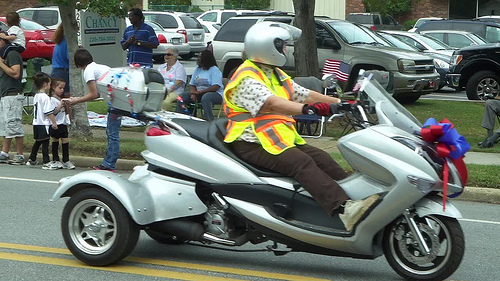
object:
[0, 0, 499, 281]
picture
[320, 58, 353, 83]
flag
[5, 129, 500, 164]
sidewalk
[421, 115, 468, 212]
ribbon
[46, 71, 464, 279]
vehicle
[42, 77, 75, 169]
girl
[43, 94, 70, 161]
uniform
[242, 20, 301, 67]
helmet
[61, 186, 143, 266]
tire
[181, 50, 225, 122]
spectator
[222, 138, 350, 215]
pants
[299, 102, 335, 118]
glove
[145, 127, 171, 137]
taillight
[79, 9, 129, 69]
sign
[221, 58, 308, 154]
vest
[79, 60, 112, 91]
shirt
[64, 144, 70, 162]
socks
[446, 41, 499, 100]
truck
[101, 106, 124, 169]
jeans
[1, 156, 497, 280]
street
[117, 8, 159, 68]
man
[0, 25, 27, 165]
father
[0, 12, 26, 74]
child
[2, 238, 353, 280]
line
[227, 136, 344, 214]
lef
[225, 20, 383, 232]
rider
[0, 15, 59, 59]
car